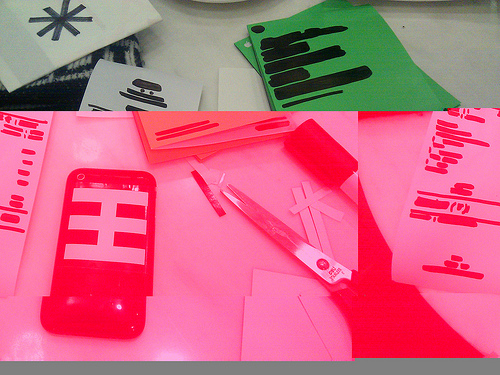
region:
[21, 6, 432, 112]
small cards with black marker designs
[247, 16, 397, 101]
mostly thick lines on green paper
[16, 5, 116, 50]
star drawn on white card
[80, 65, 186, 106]
horizontal lines and dots on paper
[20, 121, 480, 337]
objects highlighted in pink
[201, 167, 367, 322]
scissors with tips slightly apart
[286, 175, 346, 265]
thin strips of paper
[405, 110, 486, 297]
receipt with items crossed out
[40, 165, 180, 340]
container with bold horizontal lines connected with bold vertical line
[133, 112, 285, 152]
colored paper with lines across the bottom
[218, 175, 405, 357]
Scissors on top of papers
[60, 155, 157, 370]
Cellphone with white lines on the back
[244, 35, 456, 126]
Green papers with black marks on top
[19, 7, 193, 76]
Black star design on white paper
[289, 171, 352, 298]
White paper cut in small strips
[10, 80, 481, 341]
Pink area over top things on table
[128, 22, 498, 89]
Things on white table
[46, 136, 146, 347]
Iphone with white tape on it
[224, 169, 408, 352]
Metal end scissors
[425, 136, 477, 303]
Paper with black marks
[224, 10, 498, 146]
Green paper on the table.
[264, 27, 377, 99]
Black markings on green paper.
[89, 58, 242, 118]
White paper on table.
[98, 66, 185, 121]
Black marker on white paper.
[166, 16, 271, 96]
White table with paper on it.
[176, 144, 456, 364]
Red pair of scissors.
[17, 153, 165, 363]
Cell phone in red.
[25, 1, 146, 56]
Star drawn on paper.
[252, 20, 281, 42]
Black dot on green paper.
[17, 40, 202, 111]
Hat behind paper.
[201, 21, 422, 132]
Green paper with black on it.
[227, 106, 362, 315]
Silver sharp end of scissors.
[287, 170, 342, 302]
White strips of paper.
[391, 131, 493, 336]
Pink paper with black on it.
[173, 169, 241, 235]
Strip of black paper.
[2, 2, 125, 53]
White paper with black star sign on it.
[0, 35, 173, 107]
White and black hat.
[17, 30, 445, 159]
Paper on a table.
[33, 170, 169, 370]
Cell phone with the case off.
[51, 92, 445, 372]
Picture made to be a pink color.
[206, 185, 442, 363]
The bottom half of scissors.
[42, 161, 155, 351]
A red object with white design.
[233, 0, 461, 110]
Green papers with black marks.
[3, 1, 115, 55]
A star created my black marker.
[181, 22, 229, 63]
A white table underneath.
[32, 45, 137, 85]
Grey and black material.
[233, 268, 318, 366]
A blank square of paper.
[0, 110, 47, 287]
A pink piece of paper.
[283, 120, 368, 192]
A bottle of something.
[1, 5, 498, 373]
A photo of papers and objects.